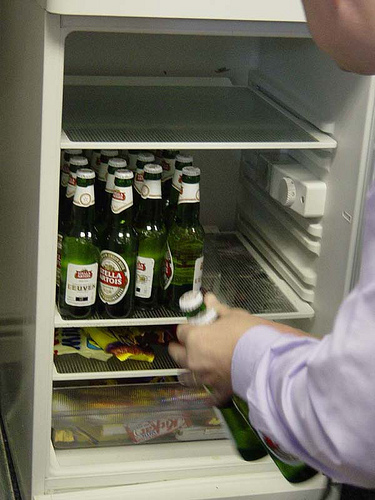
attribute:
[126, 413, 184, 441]
kitkat bar — candybar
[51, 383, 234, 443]
drawer — bottom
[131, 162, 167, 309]
bottle — alcoholic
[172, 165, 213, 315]
bottle — green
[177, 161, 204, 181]
cap — white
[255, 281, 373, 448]
shirt — purple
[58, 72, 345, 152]
shelf — empty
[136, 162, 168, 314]
bottle — green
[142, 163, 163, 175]
cap — white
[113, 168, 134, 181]
cap — white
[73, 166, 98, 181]
cap — white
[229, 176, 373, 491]
shirt — purple, lavender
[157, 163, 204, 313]
bottle — alcoholic, green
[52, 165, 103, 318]
bottle — green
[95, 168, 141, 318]
bottle — alcoholic, green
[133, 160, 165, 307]
bottle — green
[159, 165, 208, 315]
bottle — green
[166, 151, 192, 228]
bottle — green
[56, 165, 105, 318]
bottle — alcoholic, green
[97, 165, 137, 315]
bottle — green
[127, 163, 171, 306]
bottle — green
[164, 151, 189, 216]
bottle — green